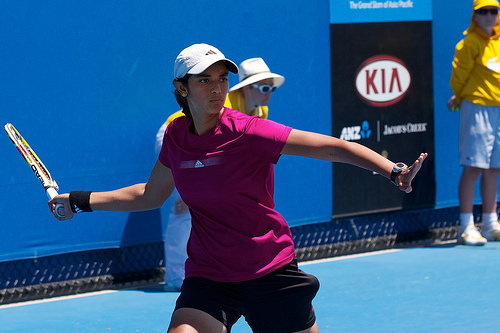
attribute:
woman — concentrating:
[46, 42, 428, 332]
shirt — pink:
[154, 105, 295, 282]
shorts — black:
[170, 253, 319, 332]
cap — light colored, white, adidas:
[170, 42, 240, 81]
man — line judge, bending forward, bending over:
[155, 54, 286, 290]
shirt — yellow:
[166, 91, 269, 126]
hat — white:
[229, 56, 285, 92]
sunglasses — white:
[251, 81, 276, 95]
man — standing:
[446, 1, 499, 247]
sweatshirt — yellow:
[449, 12, 499, 106]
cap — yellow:
[470, 0, 499, 11]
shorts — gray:
[458, 96, 499, 172]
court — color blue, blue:
[1, 234, 499, 333]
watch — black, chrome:
[388, 160, 406, 185]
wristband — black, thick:
[68, 188, 94, 214]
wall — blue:
[1, 1, 499, 257]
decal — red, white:
[354, 56, 410, 106]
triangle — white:
[193, 159, 205, 168]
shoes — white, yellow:
[453, 219, 498, 244]